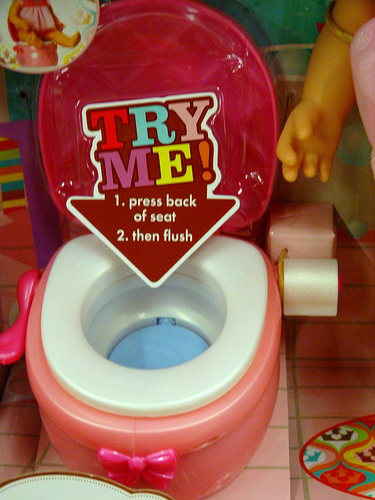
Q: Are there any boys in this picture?
A: No, there are no boys.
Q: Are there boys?
A: No, there are no boys.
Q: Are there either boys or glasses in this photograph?
A: No, there are no boys or glasses.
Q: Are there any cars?
A: No, there are no cars.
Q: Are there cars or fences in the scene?
A: No, there are no cars or fences.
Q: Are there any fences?
A: No, there are no fences.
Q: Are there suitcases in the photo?
A: No, there are no suitcases.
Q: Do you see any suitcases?
A: No, there are no suitcases.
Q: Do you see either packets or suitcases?
A: No, there are no suitcases or packets.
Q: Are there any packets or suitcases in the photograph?
A: No, there are no suitcases or packets.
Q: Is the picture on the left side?
A: Yes, the picture is on the left of the image.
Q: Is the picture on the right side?
A: No, the picture is on the left of the image.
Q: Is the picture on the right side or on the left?
A: The picture is on the left of the image.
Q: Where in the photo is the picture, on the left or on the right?
A: The picture is on the left of the image.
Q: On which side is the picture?
A: The picture is on the left of the image.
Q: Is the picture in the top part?
A: Yes, the picture is in the top of the image.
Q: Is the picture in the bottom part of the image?
A: No, the picture is in the top of the image.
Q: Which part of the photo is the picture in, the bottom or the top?
A: The picture is in the top of the image.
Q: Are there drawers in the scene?
A: No, there are no drawers.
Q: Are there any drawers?
A: No, there are no drawers.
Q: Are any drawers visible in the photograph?
A: No, there are no drawers.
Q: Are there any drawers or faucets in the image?
A: No, there are no drawers or faucets.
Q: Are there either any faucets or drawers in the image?
A: No, there are no drawers or faucets.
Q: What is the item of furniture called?
A: The piece of furniture is a shelf.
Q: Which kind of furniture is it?
A: The piece of furniture is a shelf.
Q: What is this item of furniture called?
A: This is a shelf.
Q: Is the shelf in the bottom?
A: Yes, the shelf is in the bottom of the image.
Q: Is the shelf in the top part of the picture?
A: No, the shelf is in the bottom of the image.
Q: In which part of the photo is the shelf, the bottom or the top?
A: The shelf is in the bottom of the image.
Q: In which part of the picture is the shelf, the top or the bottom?
A: The shelf is in the bottom of the image.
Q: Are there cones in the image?
A: No, there are no cones.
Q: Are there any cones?
A: No, there are no cones.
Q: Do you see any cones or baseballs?
A: No, there are no cones or baseballs.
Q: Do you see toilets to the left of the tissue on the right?
A: Yes, there is a toilet to the left of the tissue paper.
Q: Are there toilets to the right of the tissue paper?
A: No, the toilet is to the left of the tissue paper.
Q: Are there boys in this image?
A: No, there are no boys.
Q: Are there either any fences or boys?
A: No, there are no boys or fences.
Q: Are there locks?
A: No, there are no locks.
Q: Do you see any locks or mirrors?
A: No, there are no locks or mirrors.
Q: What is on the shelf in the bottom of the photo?
A: The toilet is on the shelf.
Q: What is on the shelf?
A: The toilet is on the shelf.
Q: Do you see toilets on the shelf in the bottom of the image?
A: Yes, there is a toilet on the shelf.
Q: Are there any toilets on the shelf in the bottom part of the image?
A: Yes, there is a toilet on the shelf.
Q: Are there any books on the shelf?
A: No, there is a toilet on the shelf.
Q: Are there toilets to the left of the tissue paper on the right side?
A: Yes, there is a toilet to the left of the tissue paper.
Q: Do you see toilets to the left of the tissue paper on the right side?
A: Yes, there is a toilet to the left of the tissue paper.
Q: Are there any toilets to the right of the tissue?
A: No, the toilet is to the left of the tissue.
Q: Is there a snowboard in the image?
A: No, there are no snowboards.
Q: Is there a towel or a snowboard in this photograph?
A: No, there are no snowboards or towels.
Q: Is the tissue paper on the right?
A: Yes, the tissue paper is on the right of the image.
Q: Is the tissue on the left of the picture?
A: No, the tissue is on the right of the image.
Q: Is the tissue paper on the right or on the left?
A: The tissue paper is on the right of the image.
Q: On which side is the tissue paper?
A: The tissue paper is on the right of the image.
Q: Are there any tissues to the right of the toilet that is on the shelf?
A: Yes, there is a tissue to the right of the toilet.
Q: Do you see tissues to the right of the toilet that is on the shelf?
A: Yes, there is a tissue to the right of the toilet.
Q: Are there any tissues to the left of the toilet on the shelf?
A: No, the tissue is to the right of the toilet.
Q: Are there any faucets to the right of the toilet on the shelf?
A: No, there is a tissue to the right of the toilet.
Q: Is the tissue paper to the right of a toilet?
A: Yes, the tissue paper is to the right of a toilet.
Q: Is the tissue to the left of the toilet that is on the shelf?
A: No, the tissue is to the right of the toilet.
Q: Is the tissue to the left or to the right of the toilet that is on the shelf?
A: The tissue is to the right of the toilet.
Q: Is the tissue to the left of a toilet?
A: No, the tissue is to the right of a toilet.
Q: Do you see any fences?
A: No, there are no fences.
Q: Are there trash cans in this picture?
A: No, there are no trash cans.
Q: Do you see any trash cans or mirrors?
A: No, there are no trash cans or mirrors.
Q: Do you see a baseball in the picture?
A: No, there are no baseballs.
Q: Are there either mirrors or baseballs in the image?
A: No, there are no baseballs or mirrors.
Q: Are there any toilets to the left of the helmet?
A: Yes, there is a toilet to the left of the helmet.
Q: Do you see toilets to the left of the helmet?
A: Yes, there is a toilet to the left of the helmet.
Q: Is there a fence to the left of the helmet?
A: No, there is a toilet to the left of the helmet.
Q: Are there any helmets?
A: Yes, there is a helmet.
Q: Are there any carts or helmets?
A: Yes, there is a helmet.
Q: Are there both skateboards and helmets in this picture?
A: No, there is a helmet but no skateboards.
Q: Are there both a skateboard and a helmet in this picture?
A: No, there is a helmet but no skateboards.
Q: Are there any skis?
A: No, there are no skis.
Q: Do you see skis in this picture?
A: No, there are no skis.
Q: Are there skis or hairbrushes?
A: No, there are no skis or hairbrushes.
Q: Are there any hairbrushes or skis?
A: No, there are no skis or hairbrushes.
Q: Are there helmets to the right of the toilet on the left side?
A: Yes, there is a helmet to the right of the toilet.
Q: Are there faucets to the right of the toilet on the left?
A: No, there is a helmet to the right of the toilet.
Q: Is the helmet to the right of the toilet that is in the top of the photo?
A: Yes, the helmet is to the right of the toilet.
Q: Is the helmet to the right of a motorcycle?
A: No, the helmet is to the right of the toilet.